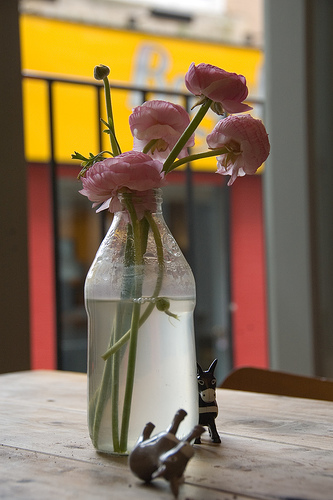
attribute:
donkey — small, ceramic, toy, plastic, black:
[195, 358, 221, 444]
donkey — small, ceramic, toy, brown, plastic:
[133, 410, 208, 491]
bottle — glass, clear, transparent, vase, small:
[86, 182, 195, 456]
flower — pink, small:
[80, 150, 164, 203]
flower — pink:
[188, 61, 251, 115]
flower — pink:
[131, 97, 193, 157]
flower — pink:
[212, 113, 270, 177]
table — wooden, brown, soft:
[4, 369, 331, 499]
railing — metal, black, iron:
[31, 72, 272, 380]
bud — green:
[91, 63, 112, 81]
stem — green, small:
[92, 68, 128, 157]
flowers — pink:
[78, 64, 270, 207]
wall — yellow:
[27, 23, 265, 170]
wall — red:
[32, 172, 269, 376]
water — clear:
[91, 297, 198, 450]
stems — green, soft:
[99, 215, 163, 451]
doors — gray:
[64, 183, 229, 373]